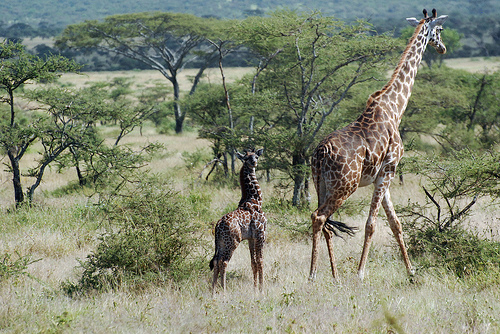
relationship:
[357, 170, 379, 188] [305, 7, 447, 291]
stomach on giraffe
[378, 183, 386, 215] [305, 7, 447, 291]
thigh of giraffe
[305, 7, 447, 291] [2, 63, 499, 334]
giraffe on ground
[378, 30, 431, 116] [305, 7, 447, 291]
neck of giraffe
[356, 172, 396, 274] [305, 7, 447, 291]
leg of giraffe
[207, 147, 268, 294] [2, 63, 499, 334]
baby on ground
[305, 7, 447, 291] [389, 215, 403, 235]
giraffe has knee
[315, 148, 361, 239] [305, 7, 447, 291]
tail of giraffe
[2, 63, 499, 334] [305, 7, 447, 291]
ground under giraffe